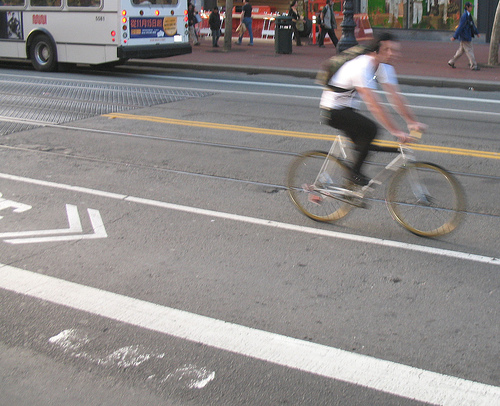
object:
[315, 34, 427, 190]
guy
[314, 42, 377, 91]
backpack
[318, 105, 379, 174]
black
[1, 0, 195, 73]
bus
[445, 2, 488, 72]
person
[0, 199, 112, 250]
arrows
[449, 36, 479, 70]
pants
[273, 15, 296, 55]
can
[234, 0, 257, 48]
man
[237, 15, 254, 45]
jeans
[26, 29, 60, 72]
tire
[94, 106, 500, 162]
line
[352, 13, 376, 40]
sign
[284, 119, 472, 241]
bicycle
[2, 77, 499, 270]
stripe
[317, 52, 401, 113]
shirt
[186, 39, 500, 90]
sidewalk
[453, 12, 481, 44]
jacket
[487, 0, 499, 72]
trunk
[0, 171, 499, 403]
lane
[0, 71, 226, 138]
grate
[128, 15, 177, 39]
ad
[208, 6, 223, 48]
people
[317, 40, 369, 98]
sack